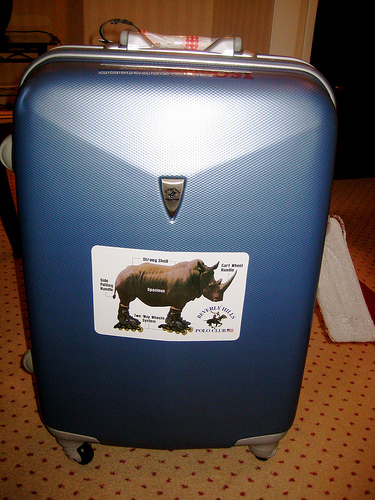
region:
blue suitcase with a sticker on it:
[13, 53, 343, 452]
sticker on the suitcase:
[81, 225, 265, 366]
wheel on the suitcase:
[53, 421, 104, 471]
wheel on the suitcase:
[246, 420, 295, 465]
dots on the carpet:
[157, 460, 220, 495]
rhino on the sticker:
[114, 252, 237, 319]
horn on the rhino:
[222, 269, 240, 299]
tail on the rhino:
[108, 270, 126, 308]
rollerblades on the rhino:
[161, 307, 194, 339]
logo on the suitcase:
[146, 167, 193, 227]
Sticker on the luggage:
[75, 238, 268, 377]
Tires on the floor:
[38, 421, 318, 473]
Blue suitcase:
[15, 122, 317, 440]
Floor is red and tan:
[124, 455, 274, 491]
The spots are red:
[105, 452, 204, 494]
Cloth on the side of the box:
[313, 202, 373, 373]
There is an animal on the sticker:
[88, 239, 264, 363]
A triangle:
[146, 163, 196, 223]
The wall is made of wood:
[29, 6, 196, 34]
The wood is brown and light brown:
[23, 3, 96, 29]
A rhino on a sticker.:
[111, 257, 236, 334]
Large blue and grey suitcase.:
[1, 42, 339, 463]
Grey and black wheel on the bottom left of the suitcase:
[62, 443, 96, 464]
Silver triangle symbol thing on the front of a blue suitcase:
[159, 176, 185, 221]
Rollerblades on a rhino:
[112, 305, 193, 335]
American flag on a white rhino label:
[226, 326, 234, 333]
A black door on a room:
[313, 2, 374, 179]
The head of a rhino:
[197, 261, 238, 301]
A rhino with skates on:
[112, 255, 237, 331]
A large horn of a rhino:
[223, 268, 236, 289]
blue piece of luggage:
[259, 167, 269, 196]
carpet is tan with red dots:
[327, 455, 332, 470]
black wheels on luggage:
[71, 438, 87, 455]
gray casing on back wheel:
[60, 423, 65, 456]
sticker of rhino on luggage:
[195, 325, 200, 337]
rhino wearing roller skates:
[163, 313, 201, 353]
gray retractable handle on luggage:
[133, 28, 199, 60]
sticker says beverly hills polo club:
[199, 306, 210, 337]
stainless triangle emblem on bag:
[159, 173, 182, 219]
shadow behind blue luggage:
[15, 275, 24, 293]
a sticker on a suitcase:
[89, 242, 255, 345]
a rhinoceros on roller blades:
[109, 261, 232, 336]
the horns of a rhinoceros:
[215, 269, 237, 290]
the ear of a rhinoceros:
[197, 259, 206, 272]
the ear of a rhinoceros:
[212, 259, 221, 271]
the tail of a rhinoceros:
[111, 287, 120, 300]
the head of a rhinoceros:
[192, 255, 238, 304]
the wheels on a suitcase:
[51, 432, 102, 473]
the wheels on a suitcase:
[246, 437, 277, 466]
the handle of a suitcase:
[108, 19, 247, 64]